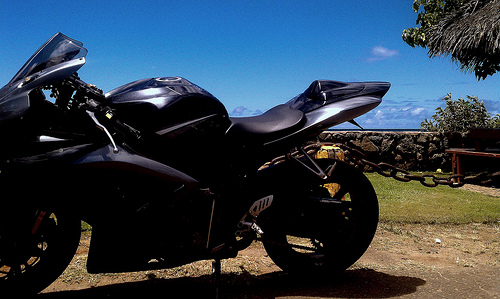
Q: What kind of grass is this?
A: This is dark green grass.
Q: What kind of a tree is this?
A: This is a dark green tree.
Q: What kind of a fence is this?
A: This is a brick fence.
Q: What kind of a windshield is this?
A: This is a black windshield.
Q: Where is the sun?
A: The sun is far back in the sky.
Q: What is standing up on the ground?
A: Black motorcycle.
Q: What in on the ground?
A: Black motorcycle.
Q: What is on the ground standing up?
A: Black motorcycle.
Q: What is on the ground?
A: Black motorcycle.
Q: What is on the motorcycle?
A: Black seat.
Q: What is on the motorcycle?
A: Black seat.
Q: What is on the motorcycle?
A: Black seat.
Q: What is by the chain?
A: Motorbike.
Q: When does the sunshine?
A: Daytime.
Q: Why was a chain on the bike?
A: To lock it up.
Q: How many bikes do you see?
A: One.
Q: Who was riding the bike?
A: No one.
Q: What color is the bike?
A: Black.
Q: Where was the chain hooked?
A: On the back of the bike.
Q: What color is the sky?
A: Blue.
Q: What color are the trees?
A: Green.